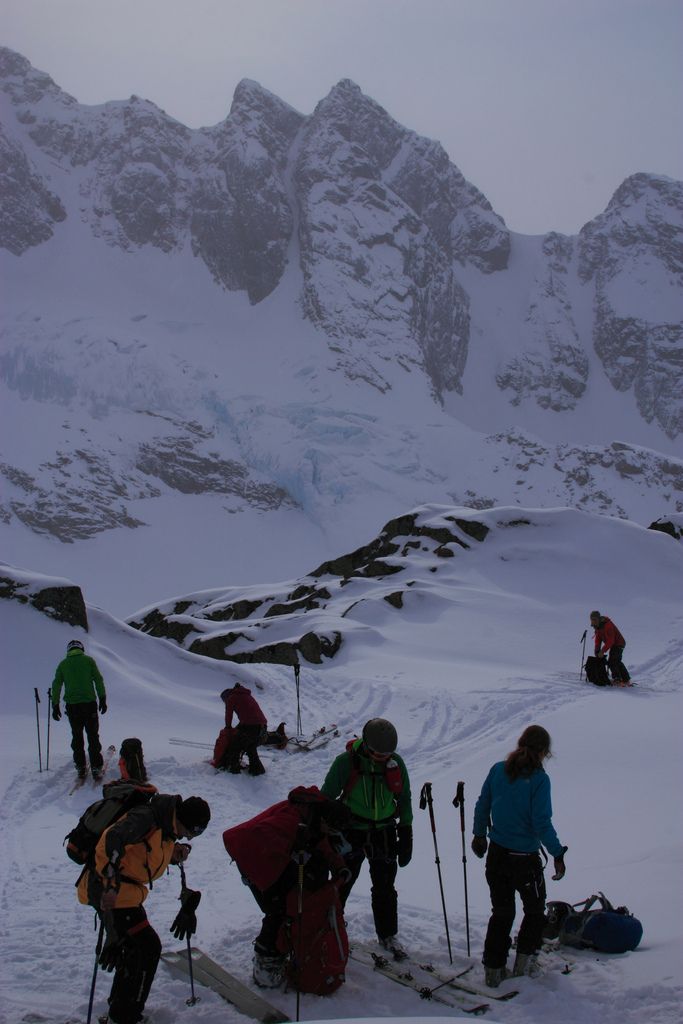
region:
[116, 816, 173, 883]
the coat is orange in color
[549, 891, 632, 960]
the bag is blue in color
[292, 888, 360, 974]
the bag is red in color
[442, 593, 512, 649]
the snow is white in color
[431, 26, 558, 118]
the sky is gray in color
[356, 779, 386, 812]
the shirt is green in color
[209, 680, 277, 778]
the guy is packing his bag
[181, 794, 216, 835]
the hat is black in color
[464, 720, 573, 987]
woman wearing blue ski jacket and black pants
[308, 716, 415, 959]
skiier wearing green ski jacket and black pants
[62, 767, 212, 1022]
skiier wearing orange jacket and black pants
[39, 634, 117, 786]
skiier wearing green jacket and black pants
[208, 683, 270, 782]
person wearing red ski jacket and black pants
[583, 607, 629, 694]
skiier wearing orange jacket and black pants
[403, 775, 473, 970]
pair of ski poles standing upright in the snow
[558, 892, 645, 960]
blue backpack laying in the snow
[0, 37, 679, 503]
jagged rocky peaks covered with snow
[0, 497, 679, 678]
low brown rocks covered in snow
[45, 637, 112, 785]
Person wearing green and black standing on skis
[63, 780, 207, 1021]
Man wearing a backpack leaning over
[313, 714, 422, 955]
Person wearing black and green with one foot on a ski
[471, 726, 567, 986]
Woman not wearing a hat.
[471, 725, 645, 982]
Woman standing by a blue duffel bag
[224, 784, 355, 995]
Person wearing a red coat leaning over to a red bag.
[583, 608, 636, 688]
Person wearing red picking up a black bag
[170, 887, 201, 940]
Single black glove hanging on a ski pole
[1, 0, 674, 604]
Rocky landscape that is covered in snow.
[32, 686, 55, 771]
Two ski poles standing in the snow.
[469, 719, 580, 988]
woman wearing a blue shirt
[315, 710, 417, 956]
man wearing a green jacket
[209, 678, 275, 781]
man wearing a red jacket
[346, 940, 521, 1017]
a set of skis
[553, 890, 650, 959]
a blue duffel bag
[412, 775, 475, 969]
set of ski poles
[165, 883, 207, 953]
a mans glove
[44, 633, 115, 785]
man wearing black pants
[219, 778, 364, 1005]
woman looking in a red bag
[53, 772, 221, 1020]
man wearing a back pack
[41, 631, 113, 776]
a person is standing up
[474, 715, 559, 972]
a person is standing up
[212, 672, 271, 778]
a person is standing up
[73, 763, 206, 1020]
a person is standing up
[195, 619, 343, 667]
a snow covered rock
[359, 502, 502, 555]
a snow covered rock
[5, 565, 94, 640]
a snow covered rock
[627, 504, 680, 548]
a snow covered rock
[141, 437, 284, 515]
a snow covered rock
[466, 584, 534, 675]
white snow on the ground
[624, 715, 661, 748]
white snow on the ground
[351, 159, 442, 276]
white snow on the ground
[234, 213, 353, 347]
white snow on the ground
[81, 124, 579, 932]
this is a mountain range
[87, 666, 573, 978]
the people are grouped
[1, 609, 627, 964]
the people are skiing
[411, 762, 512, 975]
the poles are stuck in the snow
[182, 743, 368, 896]
the snow is deep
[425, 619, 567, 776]
the snow is white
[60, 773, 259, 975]
the jacket is orange and black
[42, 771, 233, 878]
the man has a backpack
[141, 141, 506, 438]
the mountains are brown and white